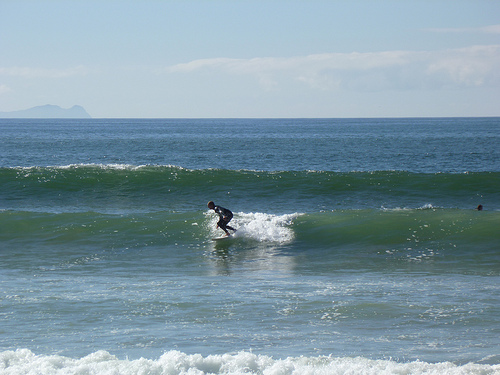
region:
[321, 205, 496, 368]
water is blue and clear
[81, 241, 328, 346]
water is blue and clear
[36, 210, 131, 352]
water is blue and clear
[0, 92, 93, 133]
a mountain is on the horizon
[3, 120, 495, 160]
the ocean is a deep blue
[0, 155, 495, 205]
a wave is about to break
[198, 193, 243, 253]
a surfer is riding a wave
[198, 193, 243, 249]
the surfer has a wet suit on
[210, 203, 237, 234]
the surfer's wetsuit is black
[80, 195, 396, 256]
the surfer caught a wave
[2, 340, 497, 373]
the water is cream when it hits the beach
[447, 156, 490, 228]
a surfer is between the waves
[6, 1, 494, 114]
the sky is blue with puffy waves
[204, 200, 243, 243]
surfing in the ocean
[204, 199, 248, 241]
surfer in the beachie waters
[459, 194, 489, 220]
a person swimming in the ocean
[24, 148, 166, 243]
multiple waves in the ocean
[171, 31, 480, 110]
blue sky with cloud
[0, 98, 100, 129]
a mountain in the distance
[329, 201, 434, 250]
splashes of water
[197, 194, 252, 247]
fast adventures surfer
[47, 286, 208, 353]
chrystal clear water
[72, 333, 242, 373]
incoming waves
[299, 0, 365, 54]
part of the sky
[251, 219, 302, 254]
part of a water splash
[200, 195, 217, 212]
head of the swimmer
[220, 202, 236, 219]
part of a swimming costume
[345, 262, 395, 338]
part of a water surface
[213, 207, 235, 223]
part of the left hand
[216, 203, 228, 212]
back of a man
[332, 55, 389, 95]
part of a cloud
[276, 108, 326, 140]
part of a water body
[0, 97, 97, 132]
mountains are on the horizon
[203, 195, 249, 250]
a surfer catching a wave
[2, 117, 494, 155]
the ocean is dark blue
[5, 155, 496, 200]
a wave is behind the surfer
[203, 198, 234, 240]
the surfer is wearing a wetsuit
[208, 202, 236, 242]
the wetsuit is black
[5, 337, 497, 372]
cream of the wave is hitting the beach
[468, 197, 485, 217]
a surfer is waiting behind a wave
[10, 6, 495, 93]
a sky is blue with puffy clouds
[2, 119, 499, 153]
the ocean has calm with ripples